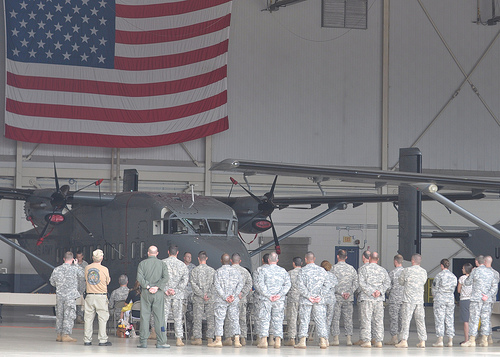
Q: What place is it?
A: It is a hangar.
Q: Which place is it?
A: It is a hangar.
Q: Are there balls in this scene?
A: No, there are no balls.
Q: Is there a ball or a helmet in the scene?
A: No, there are no balls or helmets.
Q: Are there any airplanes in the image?
A: Yes, there is an airplane.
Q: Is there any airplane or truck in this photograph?
A: Yes, there is an airplane.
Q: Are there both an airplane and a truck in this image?
A: No, there is an airplane but no trucks.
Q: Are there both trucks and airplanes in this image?
A: No, there is an airplane but no trucks.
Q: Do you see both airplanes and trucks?
A: No, there is an airplane but no trucks.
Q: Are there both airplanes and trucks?
A: No, there is an airplane but no trucks.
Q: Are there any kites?
A: No, there are no kites.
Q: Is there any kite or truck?
A: No, there are no kites or trucks.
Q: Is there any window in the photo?
A: Yes, there is a window.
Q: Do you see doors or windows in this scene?
A: Yes, there is a window.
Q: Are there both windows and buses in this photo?
A: No, there is a window but no buses.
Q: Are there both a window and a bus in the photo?
A: No, there is a window but no buses.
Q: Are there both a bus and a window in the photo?
A: No, there is a window but no buses.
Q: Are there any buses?
A: No, there are no buses.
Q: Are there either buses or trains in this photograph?
A: No, there are no buses or trains.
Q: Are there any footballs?
A: No, there are no footballs.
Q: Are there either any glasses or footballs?
A: No, there are no footballs or glasses.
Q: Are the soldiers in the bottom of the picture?
A: Yes, the soldiers are in the bottom of the image.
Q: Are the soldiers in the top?
A: No, the soldiers are in the bottom of the image.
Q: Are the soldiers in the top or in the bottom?
A: The soldiers are in the bottom of the image.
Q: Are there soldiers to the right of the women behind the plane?
A: Yes, there are soldiers to the right of the women.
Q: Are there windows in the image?
A: Yes, there is a window.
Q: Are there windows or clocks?
A: Yes, there is a window.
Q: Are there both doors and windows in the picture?
A: Yes, there are both a window and a door.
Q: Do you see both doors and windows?
A: Yes, there are both a window and a door.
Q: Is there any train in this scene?
A: No, there are no trains.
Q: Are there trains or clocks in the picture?
A: No, there are no trains or clocks.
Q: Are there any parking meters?
A: No, there are no parking meters.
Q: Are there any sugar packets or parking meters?
A: No, there are no parking meters or sugar packets.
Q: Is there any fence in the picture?
A: No, there are no fences.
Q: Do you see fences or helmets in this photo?
A: No, there are no fences or helmets.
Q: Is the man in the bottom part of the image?
A: Yes, the man is in the bottom of the image.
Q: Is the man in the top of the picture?
A: No, the man is in the bottom of the image.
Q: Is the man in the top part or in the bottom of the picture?
A: The man is in the bottom of the image.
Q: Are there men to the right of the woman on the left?
A: Yes, there is a man to the right of the woman.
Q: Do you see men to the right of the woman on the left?
A: Yes, there is a man to the right of the woman.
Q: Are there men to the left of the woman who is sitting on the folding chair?
A: No, the man is to the right of the woman.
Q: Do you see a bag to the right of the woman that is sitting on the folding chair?
A: No, there is a man to the right of the woman.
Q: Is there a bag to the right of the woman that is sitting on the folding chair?
A: No, there is a man to the right of the woman.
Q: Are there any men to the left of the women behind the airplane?
A: Yes, there is a man to the left of the women.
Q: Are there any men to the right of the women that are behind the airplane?
A: No, the man is to the left of the women.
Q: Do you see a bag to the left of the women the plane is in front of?
A: No, there is a man to the left of the women.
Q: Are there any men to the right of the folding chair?
A: Yes, there is a man to the right of the folding chair.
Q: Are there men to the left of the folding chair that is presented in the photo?
A: No, the man is to the right of the folding chair.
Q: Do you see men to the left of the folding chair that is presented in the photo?
A: No, the man is to the right of the folding chair.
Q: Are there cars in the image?
A: No, there are no cars.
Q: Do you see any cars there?
A: No, there are no cars.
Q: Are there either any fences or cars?
A: No, there are no cars or fences.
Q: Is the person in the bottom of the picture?
A: Yes, the person is in the bottom of the image.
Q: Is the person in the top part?
A: No, the person is in the bottom of the image.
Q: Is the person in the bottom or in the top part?
A: The person is in the bottom of the image.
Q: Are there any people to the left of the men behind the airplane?
A: Yes, there is a person to the left of the men.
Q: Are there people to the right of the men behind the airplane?
A: No, the person is to the left of the men.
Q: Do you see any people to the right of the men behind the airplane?
A: No, the person is to the left of the men.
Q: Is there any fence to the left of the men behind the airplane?
A: No, there is a person to the left of the men.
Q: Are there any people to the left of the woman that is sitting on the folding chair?
A: Yes, there is a person to the left of the woman.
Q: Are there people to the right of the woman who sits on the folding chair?
A: No, the person is to the left of the woman.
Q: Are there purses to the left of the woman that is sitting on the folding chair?
A: No, there is a person to the left of the woman.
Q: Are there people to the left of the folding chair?
A: Yes, there is a person to the left of the folding chair.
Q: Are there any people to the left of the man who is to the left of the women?
A: Yes, there is a person to the left of the man.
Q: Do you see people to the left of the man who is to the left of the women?
A: Yes, there is a person to the left of the man.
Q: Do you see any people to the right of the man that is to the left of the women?
A: No, the person is to the left of the man.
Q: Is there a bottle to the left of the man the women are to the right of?
A: No, there is a person to the left of the man.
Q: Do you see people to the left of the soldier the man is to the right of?
A: Yes, there is a person to the left of the soldier.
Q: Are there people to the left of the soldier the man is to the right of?
A: Yes, there is a person to the left of the soldier.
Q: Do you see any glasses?
A: No, there are no glasses.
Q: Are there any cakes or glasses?
A: No, there are no glasses or cakes.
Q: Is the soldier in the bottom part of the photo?
A: Yes, the soldier is in the bottom of the image.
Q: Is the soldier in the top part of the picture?
A: No, the soldier is in the bottom of the image.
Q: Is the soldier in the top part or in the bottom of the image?
A: The soldier is in the bottom of the image.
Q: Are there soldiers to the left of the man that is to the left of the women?
A: Yes, there is a soldier to the left of the man.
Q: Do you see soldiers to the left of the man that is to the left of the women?
A: Yes, there is a soldier to the left of the man.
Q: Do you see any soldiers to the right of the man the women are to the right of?
A: No, the soldier is to the left of the man.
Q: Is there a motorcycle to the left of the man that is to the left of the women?
A: No, there is a soldier to the left of the man.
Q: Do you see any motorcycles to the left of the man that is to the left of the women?
A: No, there is a soldier to the left of the man.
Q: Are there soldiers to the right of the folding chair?
A: Yes, there is a soldier to the right of the folding chair.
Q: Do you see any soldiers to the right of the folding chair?
A: Yes, there is a soldier to the right of the folding chair.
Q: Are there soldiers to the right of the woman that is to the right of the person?
A: Yes, there is a soldier to the right of the woman.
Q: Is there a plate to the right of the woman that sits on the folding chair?
A: No, there is a soldier to the right of the woman.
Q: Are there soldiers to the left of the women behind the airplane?
A: Yes, there is a soldier to the left of the women.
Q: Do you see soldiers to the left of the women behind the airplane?
A: Yes, there is a soldier to the left of the women.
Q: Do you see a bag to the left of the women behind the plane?
A: No, there is a soldier to the left of the women.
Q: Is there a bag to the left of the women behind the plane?
A: No, there is a soldier to the left of the women.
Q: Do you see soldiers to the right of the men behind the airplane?
A: Yes, there is a soldier to the right of the men.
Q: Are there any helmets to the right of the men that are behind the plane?
A: No, there is a soldier to the right of the men.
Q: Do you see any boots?
A: Yes, there are boots.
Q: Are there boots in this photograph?
A: Yes, there are boots.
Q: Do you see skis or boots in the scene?
A: Yes, there are boots.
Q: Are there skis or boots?
A: Yes, there are boots.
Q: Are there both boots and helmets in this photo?
A: No, there are boots but no helmets.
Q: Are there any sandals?
A: No, there are no sandals.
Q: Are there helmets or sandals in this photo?
A: No, there are no sandals or helmets.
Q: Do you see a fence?
A: No, there are no fences.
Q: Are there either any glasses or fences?
A: No, there are no fences or glasses.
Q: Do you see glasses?
A: No, there are no glasses.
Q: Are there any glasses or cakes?
A: No, there are no glasses or cakes.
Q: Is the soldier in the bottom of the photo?
A: Yes, the soldier is in the bottom of the image.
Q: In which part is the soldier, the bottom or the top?
A: The soldier is in the bottom of the image.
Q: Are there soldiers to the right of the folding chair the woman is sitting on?
A: Yes, there is a soldier to the right of the folding chair.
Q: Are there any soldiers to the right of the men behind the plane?
A: Yes, there is a soldier to the right of the men.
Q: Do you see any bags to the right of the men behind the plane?
A: No, there is a soldier to the right of the men.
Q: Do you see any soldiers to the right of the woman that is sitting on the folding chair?
A: Yes, there is a soldier to the right of the woman.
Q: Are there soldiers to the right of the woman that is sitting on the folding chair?
A: Yes, there is a soldier to the right of the woman.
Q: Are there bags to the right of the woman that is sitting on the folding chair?
A: No, there is a soldier to the right of the woman.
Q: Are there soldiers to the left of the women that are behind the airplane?
A: Yes, there is a soldier to the left of the women.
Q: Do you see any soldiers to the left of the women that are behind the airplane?
A: Yes, there is a soldier to the left of the women.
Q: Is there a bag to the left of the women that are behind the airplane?
A: No, there is a soldier to the left of the women.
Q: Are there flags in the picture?
A: Yes, there is a flag.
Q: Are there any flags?
A: Yes, there is a flag.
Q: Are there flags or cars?
A: Yes, there is a flag.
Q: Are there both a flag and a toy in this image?
A: No, there is a flag but no toys.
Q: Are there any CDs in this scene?
A: No, there are no cds.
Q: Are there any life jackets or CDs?
A: No, there are no CDs or life jackets.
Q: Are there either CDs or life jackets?
A: No, there are no CDs or life jackets.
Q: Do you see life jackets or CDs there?
A: No, there are no CDs or life jackets.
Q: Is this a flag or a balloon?
A: This is a flag.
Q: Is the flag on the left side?
A: Yes, the flag is on the left of the image.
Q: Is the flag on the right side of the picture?
A: No, the flag is on the left of the image.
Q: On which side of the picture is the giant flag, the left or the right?
A: The flag is on the left of the image.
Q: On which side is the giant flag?
A: The flag is on the left of the image.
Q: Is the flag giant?
A: Yes, the flag is giant.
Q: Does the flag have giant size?
A: Yes, the flag is giant.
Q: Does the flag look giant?
A: Yes, the flag is giant.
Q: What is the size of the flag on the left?
A: The flag is giant.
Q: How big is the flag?
A: The flag is giant.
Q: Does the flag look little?
A: No, the flag is giant.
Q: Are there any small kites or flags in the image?
A: No, there is a flag but it is giant.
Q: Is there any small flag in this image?
A: No, there is a flag but it is giant.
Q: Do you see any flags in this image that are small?
A: No, there is a flag but it is giant.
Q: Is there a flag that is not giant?
A: No, there is a flag but it is giant.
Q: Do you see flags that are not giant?
A: No, there is a flag but it is giant.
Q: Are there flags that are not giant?
A: No, there is a flag but it is giant.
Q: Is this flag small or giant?
A: The flag is giant.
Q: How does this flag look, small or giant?
A: The flag is giant.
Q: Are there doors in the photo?
A: Yes, there is a door.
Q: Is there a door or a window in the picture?
A: Yes, there is a door.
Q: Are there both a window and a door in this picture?
A: Yes, there are both a door and a window.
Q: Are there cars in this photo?
A: No, there are no cars.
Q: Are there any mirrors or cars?
A: No, there are no cars or mirrors.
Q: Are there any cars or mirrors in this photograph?
A: No, there are no cars or mirrors.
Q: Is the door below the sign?
A: Yes, the door is below the sign.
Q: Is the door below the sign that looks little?
A: Yes, the door is below the sign.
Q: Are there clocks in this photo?
A: No, there are no clocks.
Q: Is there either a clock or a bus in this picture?
A: No, there are no clocks or buses.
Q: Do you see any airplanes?
A: Yes, there is an airplane.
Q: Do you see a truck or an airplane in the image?
A: Yes, there is an airplane.